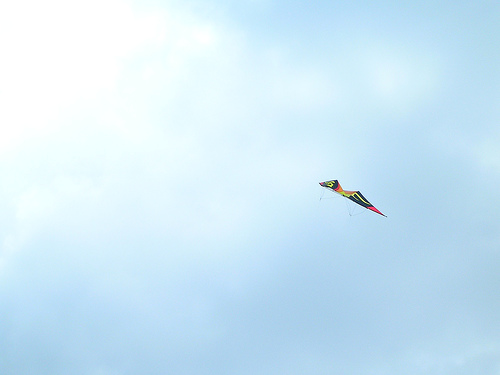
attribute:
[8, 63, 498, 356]
sky — blue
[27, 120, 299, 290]
clouds — minimal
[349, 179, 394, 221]
wing — red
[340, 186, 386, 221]
wing — black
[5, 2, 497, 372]
sky — clear, blue, white, cloudy, hazy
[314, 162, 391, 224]
kite — multi colored, blue, red, yellow, orange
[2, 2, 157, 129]
clouds — white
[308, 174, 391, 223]
glider — white, red, black, orange, green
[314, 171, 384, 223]
kite — multi-colored, red, black, yellow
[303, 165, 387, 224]
kite — red, black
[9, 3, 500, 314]
sun — bright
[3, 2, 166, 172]
clouds — white